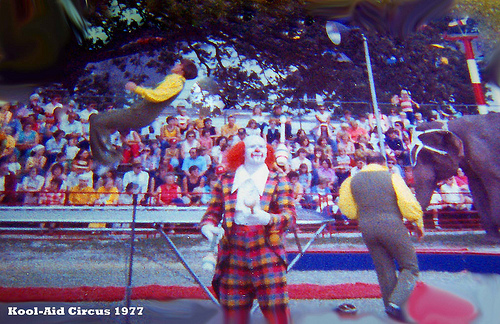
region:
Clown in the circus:
[193, 118, 318, 320]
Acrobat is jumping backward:
[70, 40, 205, 190]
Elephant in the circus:
[397, 95, 497, 252]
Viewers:
[5, 100, 460, 200]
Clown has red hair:
[195, 120, 300, 315]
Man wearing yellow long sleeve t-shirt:
[332, 137, 428, 317]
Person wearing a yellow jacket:
[61, 165, 96, 200]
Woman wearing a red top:
[151, 170, 187, 215]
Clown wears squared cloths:
[186, 120, 311, 320]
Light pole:
[321, 11, 406, 156]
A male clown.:
[219, 123, 282, 179]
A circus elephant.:
[395, 106, 490, 201]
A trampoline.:
[8, 181, 198, 230]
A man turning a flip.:
[85, 55, 208, 152]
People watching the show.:
[147, 136, 228, 196]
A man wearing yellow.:
[72, 173, 99, 208]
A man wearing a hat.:
[70, 154, 95, 180]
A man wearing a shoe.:
[367, 272, 426, 321]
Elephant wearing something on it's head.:
[400, 118, 466, 165]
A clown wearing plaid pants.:
[213, 224, 300, 301]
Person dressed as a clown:
[195, 118, 306, 323]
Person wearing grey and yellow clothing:
[63, 49, 227, 189]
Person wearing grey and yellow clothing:
[317, 136, 444, 323]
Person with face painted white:
[201, 111, 301, 322]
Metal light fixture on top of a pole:
[311, 8, 383, 184]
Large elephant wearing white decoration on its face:
[377, 98, 499, 225]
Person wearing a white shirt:
[117, 156, 150, 201]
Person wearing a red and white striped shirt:
[388, 76, 426, 127]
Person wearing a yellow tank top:
[155, 109, 184, 144]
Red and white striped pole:
[430, 21, 498, 132]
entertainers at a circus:
[89, 43, 469, 318]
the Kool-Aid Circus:
[8, 11, 498, 322]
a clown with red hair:
[198, 121, 318, 321]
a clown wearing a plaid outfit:
[178, 133, 320, 320]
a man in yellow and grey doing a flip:
[76, 40, 205, 195]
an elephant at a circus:
[391, 93, 498, 266]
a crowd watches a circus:
[7, 80, 498, 226]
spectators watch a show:
[1, 86, 493, 248]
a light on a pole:
[316, 20, 418, 206]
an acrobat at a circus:
[64, 27, 214, 209]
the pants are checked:
[221, 240, 303, 307]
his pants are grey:
[358, 213, 428, 315]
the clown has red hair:
[213, 134, 290, 173]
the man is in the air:
[89, 45, 193, 176]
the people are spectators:
[17, 96, 359, 189]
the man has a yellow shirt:
[116, 64, 186, 102]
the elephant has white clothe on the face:
[406, 128, 468, 168]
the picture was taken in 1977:
[8, 23, 495, 321]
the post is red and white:
[458, 37, 498, 112]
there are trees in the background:
[233, 48, 345, 100]